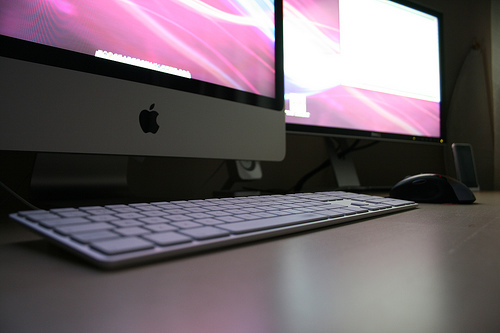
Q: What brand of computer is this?
A: Apple.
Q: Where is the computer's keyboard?
A: On the desk.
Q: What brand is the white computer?
A: Apple.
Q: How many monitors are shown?
A: Two.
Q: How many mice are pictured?
A: One.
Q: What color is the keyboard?
A: White.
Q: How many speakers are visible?
A: Two.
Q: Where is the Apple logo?
A: On the white monitor.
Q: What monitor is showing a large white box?
A: The more distant monitor.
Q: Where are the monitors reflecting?
A: On tabletop.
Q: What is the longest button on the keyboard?
A: The space bar.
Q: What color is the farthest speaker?
A: Black and silver.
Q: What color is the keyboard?
A: White.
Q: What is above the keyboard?
A: Monitor.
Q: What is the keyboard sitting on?
A: Desk.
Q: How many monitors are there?
A: Two.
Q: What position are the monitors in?
A: On.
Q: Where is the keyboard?
A: Front of monitor.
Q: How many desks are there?
A: One.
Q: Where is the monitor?
A: Desk.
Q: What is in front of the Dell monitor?
A: A phone.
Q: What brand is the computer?
A: Apple.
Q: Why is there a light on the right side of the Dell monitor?
A: It indicates that it is on.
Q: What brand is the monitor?
A: Dell.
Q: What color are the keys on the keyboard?
A: White.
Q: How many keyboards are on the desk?
A: One.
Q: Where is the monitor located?
A: To the right of the iMac.